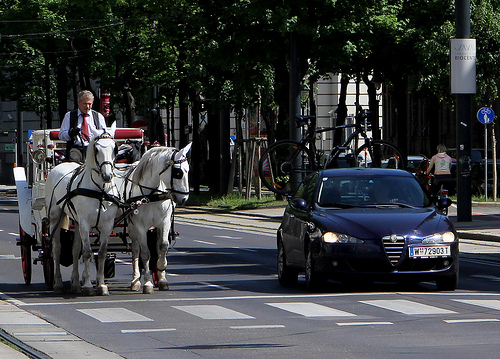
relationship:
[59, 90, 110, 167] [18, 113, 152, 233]
man on carriage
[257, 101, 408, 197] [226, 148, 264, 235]
bicycle in air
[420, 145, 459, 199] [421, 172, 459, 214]
person riding bike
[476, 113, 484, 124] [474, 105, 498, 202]
road sign on post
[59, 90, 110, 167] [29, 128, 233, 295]
man on carriage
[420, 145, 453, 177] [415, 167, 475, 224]
person on bike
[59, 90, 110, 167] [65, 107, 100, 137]
man with tie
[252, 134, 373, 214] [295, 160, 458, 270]
bicycle on car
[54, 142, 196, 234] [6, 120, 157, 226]
horses with carriage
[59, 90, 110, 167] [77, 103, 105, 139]
man with tie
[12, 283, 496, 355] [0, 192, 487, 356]
paint on road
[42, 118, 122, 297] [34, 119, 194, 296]
horses pulling a cart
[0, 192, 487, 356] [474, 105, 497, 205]
road on post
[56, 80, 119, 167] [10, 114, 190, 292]
man on cart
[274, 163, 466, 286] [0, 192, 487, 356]
car on road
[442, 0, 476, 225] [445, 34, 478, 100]
posts has stickers